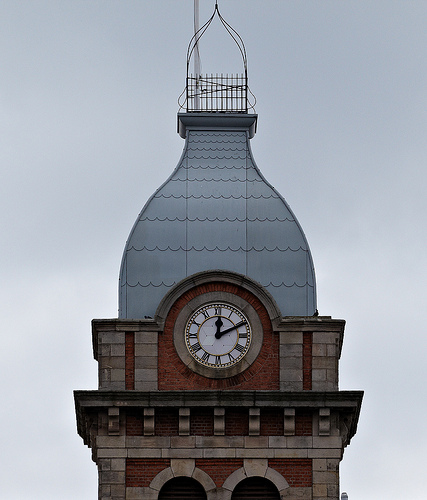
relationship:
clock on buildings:
[184, 299, 252, 367] [66, 102, 376, 497]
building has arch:
[72, 1, 364, 498] [151, 461, 215, 490]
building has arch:
[72, 1, 364, 498] [221, 462, 297, 498]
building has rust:
[72, 1, 364, 498] [167, 433, 247, 445]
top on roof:
[177, 1, 258, 115] [147, 145, 334, 270]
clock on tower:
[173, 291, 264, 379] [94, 124, 342, 389]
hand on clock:
[211, 318, 254, 338] [180, 297, 262, 373]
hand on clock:
[210, 308, 223, 342] [180, 297, 262, 373]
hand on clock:
[215, 316, 223, 340] [170, 294, 260, 372]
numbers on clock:
[189, 307, 248, 364] [184, 299, 252, 367]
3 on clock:
[239, 329, 249, 341] [168, 283, 270, 381]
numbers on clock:
[189, 307, 248, 364] [178, 267, 279, 400]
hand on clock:
[215, 316, 223, 340] [184, 299, 252, 367]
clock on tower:
[184, 299, 252, 367] [71, 14, 363, 484]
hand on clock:
[215, 322, 245, 339] [184, 299, 252, 367]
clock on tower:
[173, 291, 264, 379] [52, 278, 366, 500]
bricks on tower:
[309, 333, 336, 388] [71, 14, 363, 484]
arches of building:
[148, 464, 287, 499] [41, 28, 382, 494]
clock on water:
[173, 291, 264, 379] [326, 428, 426, 483]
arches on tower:
[105, 48, 281, 155] [77, 32, 343, 402]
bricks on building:
[247, 358, 286, 394] [72, 0, 364, 499]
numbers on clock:
[210, 308, 244, 362] [182, 301, 257, 368]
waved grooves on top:
[187, 129, 251, 164] [116, 126, 320, 313]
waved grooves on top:
[141, 165, 291, 217] [116, 126, 320, 313]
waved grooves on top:
[123, 217, 315, 320] [116, 126, 320, 313]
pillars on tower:
[280, 324, 341, 386] [71, 14, 363, 484]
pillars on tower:
[97, 329, 162, 388] [71, 14, 363, 484]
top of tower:
[172, 1, 264, 116] [71, 14, 363, 484]